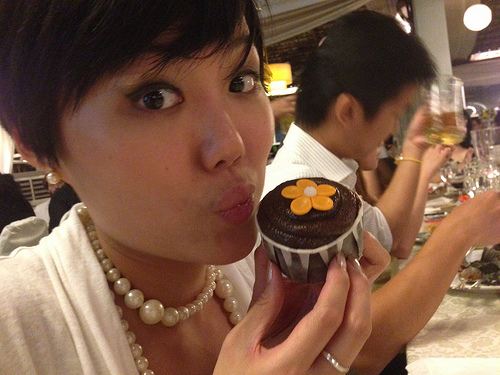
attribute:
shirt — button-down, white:
[261, 10, 442, 220]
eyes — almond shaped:
[111, 63, 273, 114]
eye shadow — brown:
[119, 81, 183, 97]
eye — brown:
[106, 67, 216, 145]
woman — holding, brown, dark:
[5, 0, 401, 374]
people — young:
[0, 0, 499, 372]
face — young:
[40, 42, 278, 267]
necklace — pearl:
[81, 217, 261, 366]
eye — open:
[124, 82, 186, 112]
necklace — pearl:
[80, 207, 268, 373]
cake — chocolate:
[259, 173, 368, 277]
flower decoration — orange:
[281, 177, 337, 209]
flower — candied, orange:
[280, 179, 336, 215]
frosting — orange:
[273, 176, 340, 215]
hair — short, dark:
[2, 6, 272, 170]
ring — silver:
[315, 348, 347, 373]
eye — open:
[94, 55, 307, 123]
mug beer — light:
[416, 75, 469, 153]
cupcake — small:
[256, 177, 364, 284]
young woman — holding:
[0, 0, 391, 375]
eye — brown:
[222, 65, 263, 99]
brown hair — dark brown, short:
[295, 24, 434, 99]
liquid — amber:
[435, 110, 467, 139]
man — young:
[288, 60, 433, 300]